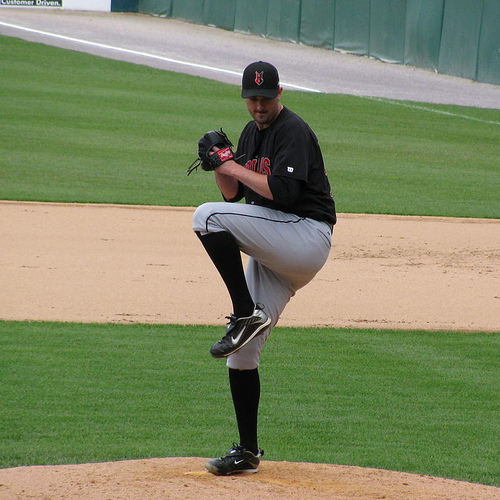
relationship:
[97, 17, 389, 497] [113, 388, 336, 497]
pitcher on mound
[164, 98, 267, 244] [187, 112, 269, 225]
glove in hand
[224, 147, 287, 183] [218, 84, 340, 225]
logo on jersey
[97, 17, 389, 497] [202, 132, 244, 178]
pitcher holding ball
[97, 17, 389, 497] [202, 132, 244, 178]
player pitching ball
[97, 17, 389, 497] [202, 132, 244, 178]
player holding ball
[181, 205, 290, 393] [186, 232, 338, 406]
one leg up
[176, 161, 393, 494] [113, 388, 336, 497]
player on mound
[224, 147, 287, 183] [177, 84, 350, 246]
logo on jersey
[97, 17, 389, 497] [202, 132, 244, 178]
pitcher throws ball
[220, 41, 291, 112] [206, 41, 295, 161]
cap on head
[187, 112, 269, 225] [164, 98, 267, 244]
hands in glove